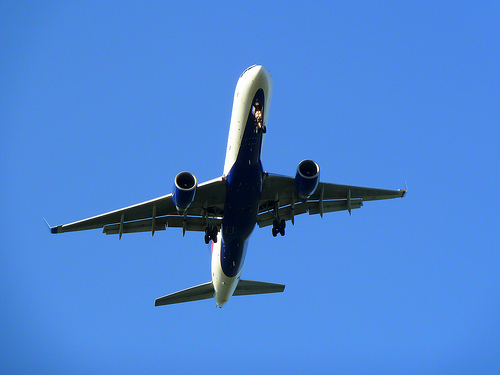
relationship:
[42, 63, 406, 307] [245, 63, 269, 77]
plane has nose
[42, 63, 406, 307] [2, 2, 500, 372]
plane in sky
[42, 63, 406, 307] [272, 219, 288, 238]
plane has wheels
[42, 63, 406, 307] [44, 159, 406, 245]
plane has wings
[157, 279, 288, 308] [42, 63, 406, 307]
tail on plane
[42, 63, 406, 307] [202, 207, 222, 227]
plane has gear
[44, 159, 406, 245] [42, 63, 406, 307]
wings on plane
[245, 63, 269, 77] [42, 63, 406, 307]
nose on plane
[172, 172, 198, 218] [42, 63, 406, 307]
engines on plane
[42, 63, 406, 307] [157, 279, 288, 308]
plane has tail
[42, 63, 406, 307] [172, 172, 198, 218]
plane has engines